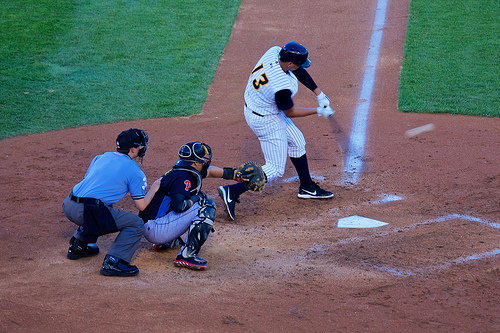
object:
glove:
[317, 92, 331, 108]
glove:
[317, 107, 333, 117]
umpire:
[60, 129, 160, 277]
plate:
[337, 214, 389, 229]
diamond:
[335, 215, 389, 229]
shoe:
[298, 183, 335, 199]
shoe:
[218, 185, 240, 220]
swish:
[303, 188, 318, 196]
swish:
[227, 186, 232, 203]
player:
[219, 41, 335, 219]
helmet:
[278, 41, 311, 68]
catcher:
[139, 141, 267, 271]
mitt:
[232, 161, 268, 190]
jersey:
[243, 45, 300, 116]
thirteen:
[252, 66, 268, 92]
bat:
[324, 107, 364, 171]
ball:
[407, 118, 433, 139]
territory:
[0, 0, 500, 333]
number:
[252, 63, 266, 73]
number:
[253, 72, 270, 90]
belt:
[243, 102, 263, 117]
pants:
[240, 105, 306, 180]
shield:
[137, 130, 148, 158]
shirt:
[72, 152, 146, 206]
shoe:
[99, 258, 140, 275]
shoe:
[65, 242, 99, 259]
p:
[183, 179, 193, 192]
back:
[242, 47, 280, 113]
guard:
[191, 199, 216, 256]